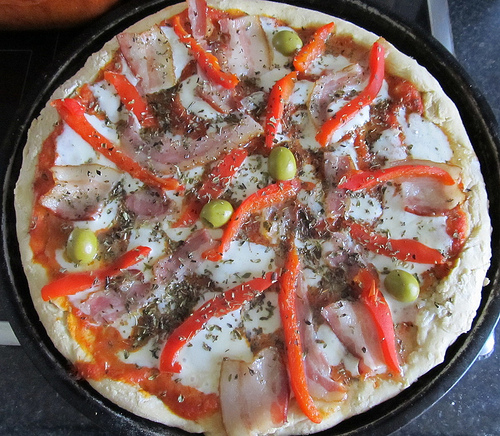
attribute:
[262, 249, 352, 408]
peppers — red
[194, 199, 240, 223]
olives — green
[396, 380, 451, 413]
tray — black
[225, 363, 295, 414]
bacon — raw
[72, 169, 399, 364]
pizza — large, white, doughy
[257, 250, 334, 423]
vegetable — long, thin, orange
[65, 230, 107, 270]
olive — small, round, green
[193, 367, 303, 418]
meat — large, thin, slice